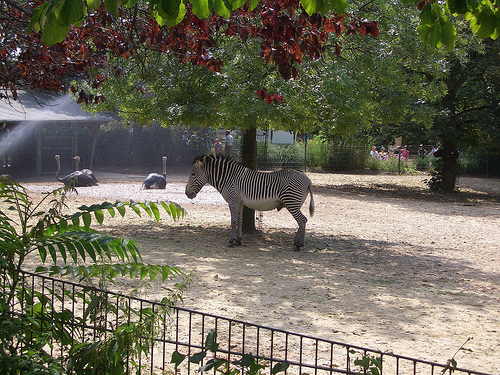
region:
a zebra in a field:
[147, 112, 496, 332]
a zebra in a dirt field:
[104, 50, 499, 371]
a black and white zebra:
[136, 98, 432, 348]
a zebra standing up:
[158, 92, 446, 292]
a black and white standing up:
[122, 62, 453, 362]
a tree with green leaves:
[129, 15, 441, 295]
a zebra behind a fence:
[29, 72, 386, 374]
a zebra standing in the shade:
[111, 0, 492, 324]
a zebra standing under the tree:
[117, 7, 499, 311]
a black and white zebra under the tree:
[91, 57, 461, 364]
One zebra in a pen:
[170, 145, 361, 256]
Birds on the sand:
[35, 140, 185, 195]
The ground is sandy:
[20, 160, 490, 370]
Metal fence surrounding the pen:
[0, 270, 473, 372]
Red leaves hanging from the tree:
[1, 5, 368, 100]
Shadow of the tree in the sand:
[63, 220, 480, 340]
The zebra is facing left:
[172, 147, 353, 253]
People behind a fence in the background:
[170, 123, 450, 173]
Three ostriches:
[37, 142, 179, 196]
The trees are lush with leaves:
[0, 0, 491, 156]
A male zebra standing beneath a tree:
[175, 148, 322, 255]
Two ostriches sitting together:
[43, 142, 108, 192]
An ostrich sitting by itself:
[133, 148, 173, 194]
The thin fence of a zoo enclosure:
[1, 252, 498, 374]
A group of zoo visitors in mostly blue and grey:
[173, 127, 240, 159]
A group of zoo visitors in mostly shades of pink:
[361, 138, 438, 167]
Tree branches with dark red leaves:
[0, 0, 377, 111]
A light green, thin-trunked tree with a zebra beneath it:
[85, 2, 410, 244]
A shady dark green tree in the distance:
[340, 0, 498, 212]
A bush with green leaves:
[0, 182, 187, 373]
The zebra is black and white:
[143, 144, 363, 274]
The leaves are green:
[10, 211, 184, 368]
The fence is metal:
[9, 241, 248, 373]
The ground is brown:
[229, 256, 394, 371]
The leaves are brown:
[14, 14, 394, 143]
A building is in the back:
[19, 89, 277, 231]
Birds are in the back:
[30, 136, 215, 234]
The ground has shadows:
[245, 248, 458, 365]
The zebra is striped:
[146, 105, 348, 274]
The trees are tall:
[164, 81, 335, 328]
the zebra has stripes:
[141, 104, 403, 328]